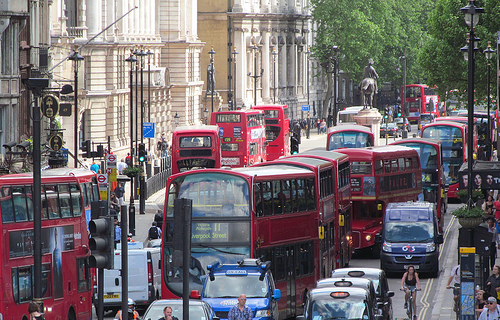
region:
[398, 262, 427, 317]
Woman riding bicycle on road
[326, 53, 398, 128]
Statue in the middle of the road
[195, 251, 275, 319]
Blue van in front of bus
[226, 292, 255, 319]
Man wearing a plaid shirt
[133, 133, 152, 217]
Stop light turned to green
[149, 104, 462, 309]
A line of double decker buses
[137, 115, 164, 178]
Blue sign near sidewalk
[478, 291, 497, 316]
Man wearing a tan cap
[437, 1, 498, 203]
Black lamp post on street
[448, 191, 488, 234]
Flower pot hanging on pole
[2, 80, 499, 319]
busy city street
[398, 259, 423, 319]
woman in black top on a bike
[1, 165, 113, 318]
bus closest to the camera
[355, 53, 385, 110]
statue in the middle of the traffic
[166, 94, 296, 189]
three buses on the side of the road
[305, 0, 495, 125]
a group of green trees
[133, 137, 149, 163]
traffic light showing green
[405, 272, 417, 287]
woman's black tank top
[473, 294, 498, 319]
man with white shirt and sunglasses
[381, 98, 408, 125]
two green traffic lights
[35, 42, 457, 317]
many red buses in photograph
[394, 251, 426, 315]
person wearing a black tank top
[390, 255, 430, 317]
person riding a bike on road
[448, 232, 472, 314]
black, yellow, white sign on road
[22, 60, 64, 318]
large street light on black pole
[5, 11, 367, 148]
street lined with beige buildings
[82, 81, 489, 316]
most red buses are two stories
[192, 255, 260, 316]
blue vehicle in photograph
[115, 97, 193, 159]
blue street sing with white writing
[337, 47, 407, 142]
statue in background of photo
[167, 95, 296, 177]
the buses are double decker.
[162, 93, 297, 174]
the buses are red.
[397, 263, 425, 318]
person riding a bicycle.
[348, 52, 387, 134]
sculpture on the street.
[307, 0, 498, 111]
the trees are green.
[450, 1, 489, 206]
the light post is green.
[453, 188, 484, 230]
potted plant on light post.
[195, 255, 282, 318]
the van is blue.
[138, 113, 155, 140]
the sign is blue.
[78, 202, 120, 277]
the traffic light is black.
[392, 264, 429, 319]
woman is on bike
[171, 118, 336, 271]
the buses are red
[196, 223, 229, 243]
the lettering is yellow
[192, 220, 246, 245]
lettering on the screen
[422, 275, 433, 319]
the lines are on the road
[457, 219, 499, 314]
the sidewalk is crowded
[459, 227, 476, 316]
signs on the post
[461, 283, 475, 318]
the map is blue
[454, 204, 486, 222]
the plant is green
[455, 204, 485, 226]
plant is in a bowl